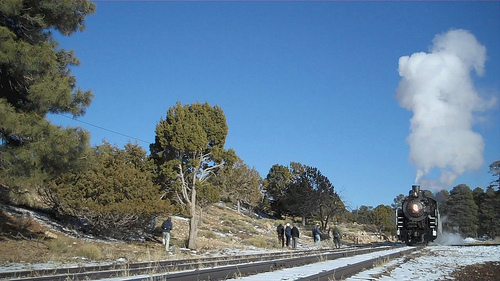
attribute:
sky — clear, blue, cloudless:
[1, 0, 499, 211]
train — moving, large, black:
[391, 179, 446, 249]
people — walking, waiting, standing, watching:
[327, 223, 345, 249]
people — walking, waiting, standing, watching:
[311, 223, 325, 243]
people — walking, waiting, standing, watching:
[290, 223, 303, 251]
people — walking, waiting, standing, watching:
[281, 220, 294, 250]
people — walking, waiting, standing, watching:
[273, 220, 286, 250]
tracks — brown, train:
[0, 242, 422, 280]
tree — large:
[273, 168, 354, 237]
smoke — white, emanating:
[387, 22, 497, 189]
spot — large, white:
[412, 200, 423, 215]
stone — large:
[42, 228, 62, 242]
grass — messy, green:
[1, 182, 376, 275]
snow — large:
[392, 234, 497, 280]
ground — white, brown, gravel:
[1, 242, 499, 280]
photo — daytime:
[1, 1, 500, 280]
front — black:
[393, 184, 433, 241]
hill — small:
[1, 173, 333, 273]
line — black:
[44, 105, 155, 152]